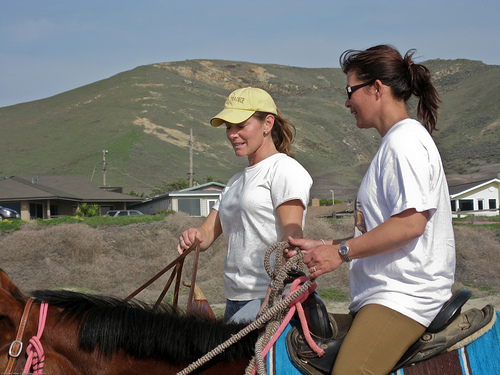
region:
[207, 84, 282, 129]
a yellow baseball cap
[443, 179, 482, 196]
part of a roof of a home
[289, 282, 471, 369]
part of a black horse saddle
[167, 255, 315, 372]
a long gray rope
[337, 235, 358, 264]
a woman's gray wristwatch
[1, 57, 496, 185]
a large mountain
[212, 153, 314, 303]
a woman's white shirt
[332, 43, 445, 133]
a woman's brown hair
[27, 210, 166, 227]
a section of green grass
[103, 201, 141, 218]
part of a vehicle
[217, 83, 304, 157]
the head of a woman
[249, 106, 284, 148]
the ear of a woman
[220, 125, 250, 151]
the nose of a woman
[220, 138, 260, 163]
the mouth of a woman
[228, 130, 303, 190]
the neck of a woman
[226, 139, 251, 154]
the lips of a woman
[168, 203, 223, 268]
the hand of a woman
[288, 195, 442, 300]
the arm of a woman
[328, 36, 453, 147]
the hair of a woman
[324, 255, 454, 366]
the leg of a woman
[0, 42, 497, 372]
two horsewomen riding in arid hills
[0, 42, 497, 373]
rider with white shirt and tan riding pants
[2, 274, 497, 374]
horse wearing leather bridle and pink halter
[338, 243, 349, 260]
wristwatch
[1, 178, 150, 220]
single story ranch style home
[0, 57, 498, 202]
hills surrounding homes in valley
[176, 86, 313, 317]
young woman wearing yellow ball cap and white tee-shirt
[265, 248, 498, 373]
western saddle on blue and gray saddle blanket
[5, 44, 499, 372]
young female rider with a single rein in each hand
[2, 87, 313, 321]
horseman reining single-handed western style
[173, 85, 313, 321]
a woman in a yellow hat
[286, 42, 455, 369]
a woman on a horse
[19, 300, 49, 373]
rope on a horse's neck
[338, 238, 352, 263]
watch on a woman's wrist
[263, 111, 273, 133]
ear of a woman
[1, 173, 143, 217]
a brown house in the distance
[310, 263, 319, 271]
ring on a woman's finger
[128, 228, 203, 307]
a woman's hand holding reigns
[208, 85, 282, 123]
a yellow hat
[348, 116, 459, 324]
the shirt is white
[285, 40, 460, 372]
A lady riding a horse wearing a watch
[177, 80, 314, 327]
A lady riding a horse wearing a yellow hat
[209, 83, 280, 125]
A yellow baseball cap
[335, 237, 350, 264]
A sliver watch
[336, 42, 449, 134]
Dark brown hair on the lady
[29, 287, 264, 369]
The black mane of the horse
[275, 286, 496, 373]
A leather saddle on the horse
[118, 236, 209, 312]
Leather reins of the horse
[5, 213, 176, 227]
a bit of green grass on the small hill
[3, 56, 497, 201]
A large hill in the background